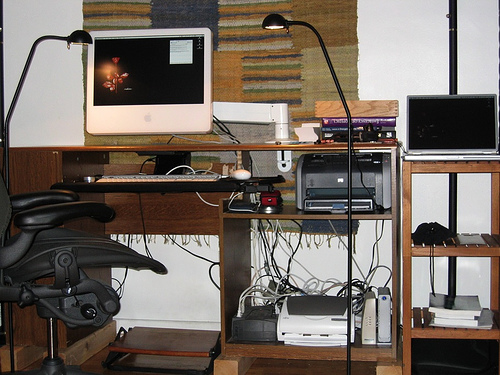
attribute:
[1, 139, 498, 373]
desk — black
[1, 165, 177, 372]
chair — black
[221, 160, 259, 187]
mouse — white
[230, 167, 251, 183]
mouse — white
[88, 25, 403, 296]
electric devices — electronic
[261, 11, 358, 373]
blacklamp — long, black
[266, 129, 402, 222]
printer — grey, black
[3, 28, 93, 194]
light — black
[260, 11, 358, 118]
light — black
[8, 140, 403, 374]
desk — brown, wooden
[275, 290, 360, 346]
machine — printing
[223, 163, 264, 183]
computer mouse — white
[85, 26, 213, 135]
monitor — turned on, computer, white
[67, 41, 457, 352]
desk — black